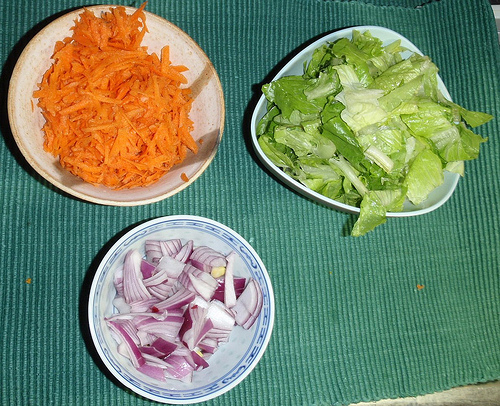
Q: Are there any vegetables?
A: Yes, there are vegetables.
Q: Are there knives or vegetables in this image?
A: Yes, there are vegetables.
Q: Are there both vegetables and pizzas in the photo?
A: No, there are vegetables but no pizzas.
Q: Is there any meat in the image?
A: No, there is no meat.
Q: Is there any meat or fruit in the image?
A: No, there are no meat or fruits.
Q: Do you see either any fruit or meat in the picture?
A: No, there are no meat or fruits.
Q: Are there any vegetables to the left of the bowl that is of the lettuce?
A: Yes, there are vegetables to the left of the bowl.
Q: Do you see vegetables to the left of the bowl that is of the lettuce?
A: Yes, there are vegetables to the left of the bowl.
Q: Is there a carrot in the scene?
A: Yes, there are carrots.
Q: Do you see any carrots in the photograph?
A: Yes, there are carrots.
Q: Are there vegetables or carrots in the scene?
A: Yes, there are carrots.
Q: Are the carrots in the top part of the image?
A: Yes, the carrots are in the top of the image.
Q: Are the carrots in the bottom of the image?
A: No, the carrots are in the top of the image.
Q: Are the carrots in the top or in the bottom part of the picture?
A: The carrots are in the top of the image.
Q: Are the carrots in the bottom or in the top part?
A: The carrots are in the top of the image.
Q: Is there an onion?
A: Yes, there are onions.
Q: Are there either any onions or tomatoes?
A: Yes, there are onions.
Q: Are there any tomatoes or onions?
A: Yes, there are onions.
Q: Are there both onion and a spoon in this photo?
A: No, there are onions but no spoons.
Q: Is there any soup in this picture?
A: No, there is no soup.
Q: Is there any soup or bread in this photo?
A: No, there are no soup or breads.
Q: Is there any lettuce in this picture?
A: Yes, there is lettuce.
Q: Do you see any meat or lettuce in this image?
A: Yes, there is lettuce.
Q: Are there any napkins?
A: No, there are no napkins.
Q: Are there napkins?
A: No, there are no napkins.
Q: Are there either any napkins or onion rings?
A: No, there are no napkins or onion rings.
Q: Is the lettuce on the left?
A: No, the lettuce is on the right of the image.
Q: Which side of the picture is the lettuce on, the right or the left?
A: The lettuce is on the right of the image.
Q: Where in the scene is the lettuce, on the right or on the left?
A: The lettuce is on the right of the image.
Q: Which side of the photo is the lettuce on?
A: The lettuce is on the right of the image.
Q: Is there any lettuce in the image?
A: Yes, there is lettuce.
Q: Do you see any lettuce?
A: Yes, there is lettuce.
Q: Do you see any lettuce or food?
A: Yes, there is lettuce.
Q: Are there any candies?
A: No, there are no candies.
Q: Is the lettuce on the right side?
A: Yes, the lettuce is on the right of the image.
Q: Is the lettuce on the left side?
A: No, the lettuce is on the right of the image.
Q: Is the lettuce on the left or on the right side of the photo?
A: The lettuce is on the right of the image.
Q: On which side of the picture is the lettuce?
A: The lettuce is on the right of the image.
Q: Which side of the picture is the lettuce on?
A: The lettuce is on the right of the image.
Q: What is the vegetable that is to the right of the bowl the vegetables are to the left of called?
A: The vegetable is lettuce.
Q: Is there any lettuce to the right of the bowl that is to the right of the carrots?
A: Yes, there is lettuce to the right of the bowl.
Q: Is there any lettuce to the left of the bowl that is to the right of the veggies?
A: No, the lettuce is to the right of the bowl.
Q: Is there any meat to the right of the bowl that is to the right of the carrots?
A: No, there is lettuce to the right of the bowl.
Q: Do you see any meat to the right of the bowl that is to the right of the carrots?
A: No, there is lettuce to the right of the bowl.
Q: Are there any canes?
A: No, there are no canes.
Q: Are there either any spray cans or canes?
A: No, there are no canes or spray cans.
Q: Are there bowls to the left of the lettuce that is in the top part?
A: Yes, there is a bowl to the left of the lettuce.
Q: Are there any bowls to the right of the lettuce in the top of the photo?
A: No, the bowl is to the left of the lettuce.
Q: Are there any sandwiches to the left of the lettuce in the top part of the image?
A: No, there is a bowl to the left of the lettuce.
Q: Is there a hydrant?
A: No, there are no fire hydrants.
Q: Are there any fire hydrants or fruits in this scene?
A: No, there are no fire hydrants or fruits.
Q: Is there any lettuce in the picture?
A: Yes, there is lettuce.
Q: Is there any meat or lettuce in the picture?
A: Yes, there is lettuce.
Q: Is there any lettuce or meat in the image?
A: Yes, there is lettuce.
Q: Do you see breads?
A: No, there are no breads.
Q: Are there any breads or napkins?
A: No, there are no breads or napkins.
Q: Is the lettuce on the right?
A: Yes, the lettuce is on the right of the image.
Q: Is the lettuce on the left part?
A: No, the lettuce is on the right of the image.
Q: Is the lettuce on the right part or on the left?
A: The lettuce is on the right of the image.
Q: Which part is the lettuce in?
A: The lettuce is on the right of the image.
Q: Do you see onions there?
A: Yes, there are onions.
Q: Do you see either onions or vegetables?
A: Yes, there are onions.